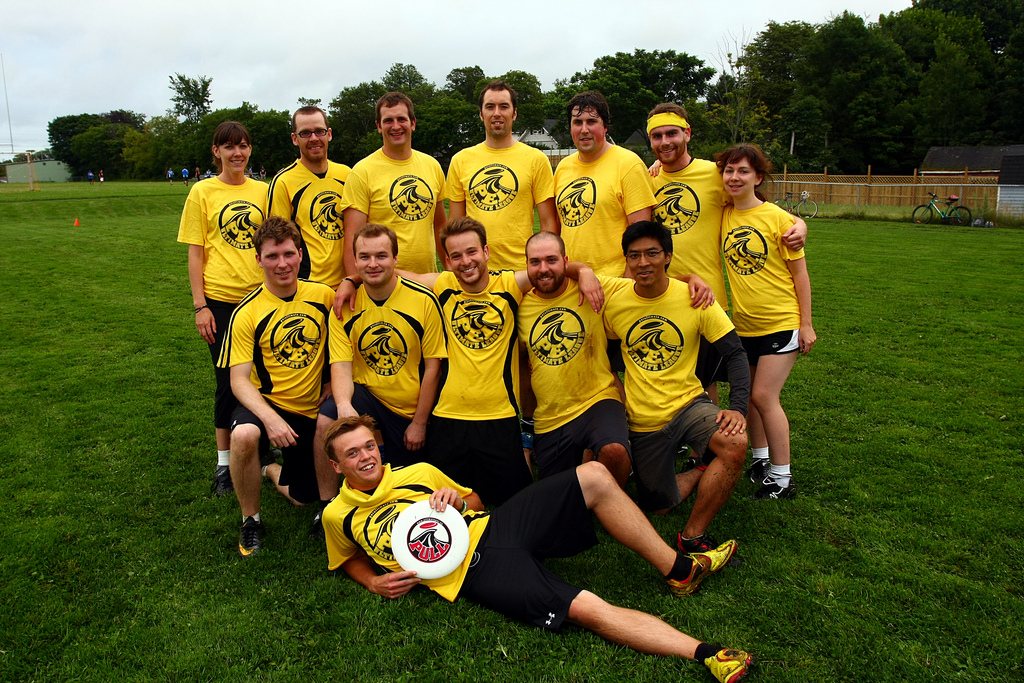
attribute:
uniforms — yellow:
[171, 144, 815, 602]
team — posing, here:
[179, 78, 820, 682]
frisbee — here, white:
[389, 496, 472, 579]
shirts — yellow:
[176, 139, 807, 601]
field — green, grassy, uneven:
[1, 180, 1021, 682]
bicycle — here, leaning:
[908, 191, 971, 228]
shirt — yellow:
[319, 459, 492, 605]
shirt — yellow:
[176, 175, 272, 310]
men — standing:
[263, 79, 731, 411]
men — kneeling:
[221, 218, 753, 562]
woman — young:
[712, 142, 816, 505]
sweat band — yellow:
[645, 113, 691, 139]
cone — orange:
[73, 212, 81, 233]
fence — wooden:
[753, 170, 1003, 221]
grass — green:
[1, 180, 1021, 682]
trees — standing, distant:
[46, 9, 1022, 183]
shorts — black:
[457, 463, 601, 630]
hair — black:
[623, 221, 671, 272]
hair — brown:
[712, 144, 768, 177]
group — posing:
[175, 79, 820, 681]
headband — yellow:
[642, 109, 691, 135]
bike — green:
[909, 190, 975, 226]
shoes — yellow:
[662, 534, 756, 680]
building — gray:
[5, 153, 75, 189]